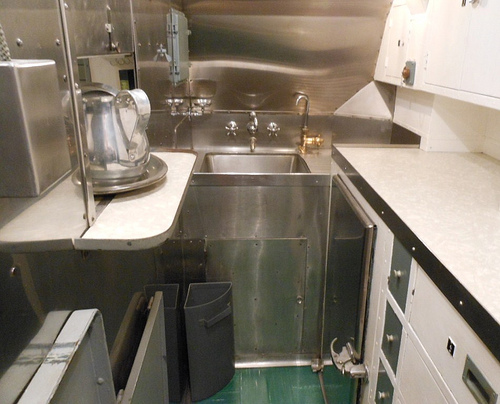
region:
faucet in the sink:
[233, 116, 269, 155]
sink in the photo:
[176, 139, 311, 191]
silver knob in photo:
[251, 109, 293, 151]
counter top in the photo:
[410, 135, 497, 215]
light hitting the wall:
[188, 26, 321, 96]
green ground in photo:
[221, 359, 308, 402]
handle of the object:
[108, 82, 163, 149]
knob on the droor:
[363, 244, 415, 311]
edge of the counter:
[313, 129, 358, 179]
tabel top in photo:
[72, 137, 209, 284]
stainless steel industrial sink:
[197, 99, 311, 178]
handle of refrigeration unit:
[324, 335, 369, 381]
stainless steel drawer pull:
[386, 264, 404, 280]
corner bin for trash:
[181, 275, 241, 400]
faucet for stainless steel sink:
[263, 122, 282, 139]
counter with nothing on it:
[342, 142, 498, 324]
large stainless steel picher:
[85, 88, 154, 187]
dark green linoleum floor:
[213, 368, 337, 403]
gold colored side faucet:
[297, 127, 326, 154]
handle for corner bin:
[194, 303, 234, 330]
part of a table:
[449, 183, 466, 204]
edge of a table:
[371, 250, 375, 272]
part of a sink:
[301, 228, 308, 255]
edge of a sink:
[248, 230, 267, 292]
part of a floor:
[295, 371, 302, 380]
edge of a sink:
[256, 172, 266, 199]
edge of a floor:
[289, 310, 292, 335]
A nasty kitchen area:
[157, 53, 287, 288]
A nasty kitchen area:
[73, 46, 384, 391]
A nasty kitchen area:
[342, 39, 459, 326]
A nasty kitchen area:
[23, 28, 192, 323]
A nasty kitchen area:
[193, 43, 439, 315]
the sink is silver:
[185, 134, 320, 179]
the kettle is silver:
[75, 72, 165, 209]